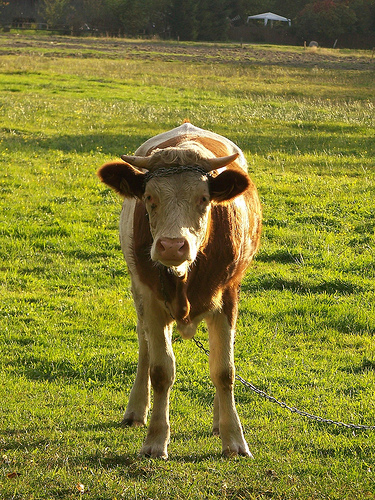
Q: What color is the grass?
A: Green.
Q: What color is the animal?
A: Brown and white.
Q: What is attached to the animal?
A: A chain.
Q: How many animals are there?
A: One.